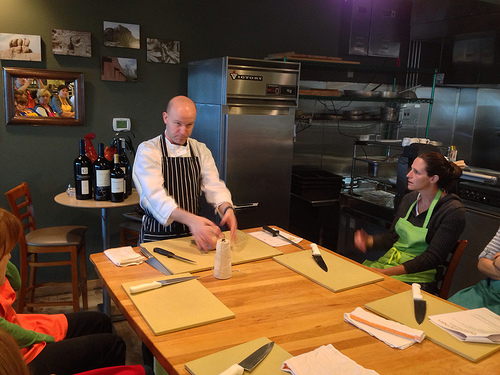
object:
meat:
[192, 220, 224, 251]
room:
[0, 0, 499, 375]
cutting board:
[139, 229, 283, 274]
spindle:
[213, 238, 233, 279]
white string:
[213, 239, 232, 280]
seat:
[24, 225, 87, 247]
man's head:
[162, 95, 198, 145]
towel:
[102, 246, 146, 267]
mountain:
[105, 22, 140, 48]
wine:
[73, 139, 132, 203]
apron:
[361, 189, 443, 283]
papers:
[343, 306, 500, 350]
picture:
[0, 22, 181, 127]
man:
[131, 94, 237, 255]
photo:
[14, 77, 77, 119]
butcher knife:
[309, 243, 328, 273]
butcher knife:
[412, 283, 427, 326]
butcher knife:
[129, 275, 201, 293]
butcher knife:
[212, 341, 275, 375]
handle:
[310, 243, 322, 256]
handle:
[412, 283, 423, 301]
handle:
[128, 281, 162, 293]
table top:
[54, 187, 143, 209]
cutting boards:
[182, 335, 294, 374]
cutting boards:
[363, 288, 499, 363]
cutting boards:
[272, 248, 384, 293]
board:
[121, 272, 235, 336]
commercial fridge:
[187, 55, 301, 230]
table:
[89, 225, 499, 375]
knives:
[221, 340, 274, 374]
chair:
[3, 182, 89, 314]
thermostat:
[112, 117, 131, 131]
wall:
[1, 0, 406, 280]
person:
[354, 150, 467, 292]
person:
[0, 205, 128, 375]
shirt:
[132, 133, 236, 225]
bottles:
[73, 138, 132, 203]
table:
[53, 187, 144, 314]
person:
[448, 228, 499, 316]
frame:
[0, 65, 88, 127]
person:
[13, 74, 35, 116]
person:
[33, 88, 56, 117]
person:
[51, 84, 76, 118]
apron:
[137, 129, 203, 246]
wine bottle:
[73, 139, 133, 203]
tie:
[388, 246, 417, 264]